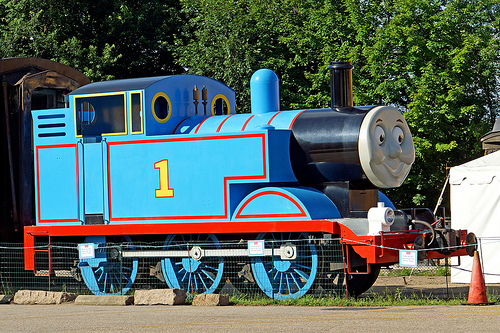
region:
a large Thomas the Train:
[8, 38, 472, 291]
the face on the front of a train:
[362, 107, 418, 194]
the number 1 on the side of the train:
[143, 147, 178, 203]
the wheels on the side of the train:
[71, 232, 321, 299]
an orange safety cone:
[454, 247, 489, 307]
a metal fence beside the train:
[12, 242, 382, 290]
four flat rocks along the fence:
[11, 286, 234, 309]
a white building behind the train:
[433, 154, 495, 319]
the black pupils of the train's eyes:
[377, 128, 405, 145]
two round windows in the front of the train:
[149, 85, 241, 126]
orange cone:
[462, 248, 494, 308]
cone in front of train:
[462, 247, 492, 305]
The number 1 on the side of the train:
[154, 159, 173, 196]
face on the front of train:
[361, 108, 413, 188]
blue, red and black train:
[0, 57, 475, 302]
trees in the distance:
[0, 0, 499, 219]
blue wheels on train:
[82, 236, 314, 298]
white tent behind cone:
[441, 144, 498, 281]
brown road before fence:
[1, 304, 498, 331]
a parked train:
[1, 54, 475, 299]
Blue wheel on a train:
[241, 218, 341, 327]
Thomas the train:
[30, 88, 396, 332]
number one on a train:
[143, 152, 200, 220]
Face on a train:
[349, 90, 446, 222]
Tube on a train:
[228, 57, 321, 123]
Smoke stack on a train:
[323, 50, 360, 110]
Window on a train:
[66, 88, 166, 148]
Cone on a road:
[451, 241, 499, 323]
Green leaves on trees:
[103, 11, 499, 100]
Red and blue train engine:
[40, 53, 428, 305]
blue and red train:
[25, 56, 480, 305]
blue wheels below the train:
[71, 236, 320, 301]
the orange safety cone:
[459, 249, 494, 307]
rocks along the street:
[10, 281, 230, 311]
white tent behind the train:
[435, 146, 498, 286]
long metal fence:
[2, 227, 499, 304]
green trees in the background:
[1, 1, 498, 106]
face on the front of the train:
[361, 106, 416, 189]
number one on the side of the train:
[141, 153, 181, 204]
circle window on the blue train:
[147, 89, 174, 124]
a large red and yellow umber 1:
[154, 157, 177, 200]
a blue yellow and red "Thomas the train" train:
[24, 76, 474, 293]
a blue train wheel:
[247, 240, 318, 297]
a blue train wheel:
[80, 242, 135, 295]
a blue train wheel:
[163, 231, 227, 298]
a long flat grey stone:
[15, 289, 72, 304]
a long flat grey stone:
[76, 293, 132, 304]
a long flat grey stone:
[127, 286, 183, 307]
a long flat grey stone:
[191, 290, 228, 308]